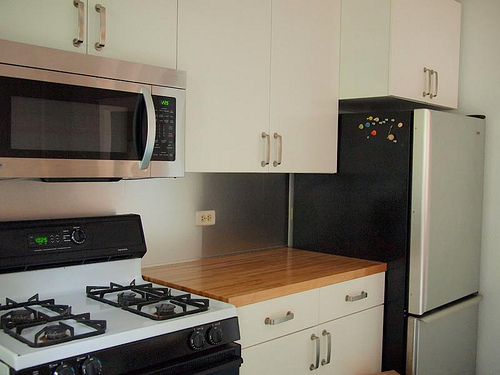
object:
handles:
[71, 0, 109, 51]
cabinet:
[179, 1, 343, 171]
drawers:
[232, 270, 386, 349]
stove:
[2, 278, 210, 347]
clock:
[24, 229, 64, 251]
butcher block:
[142, 245, 385, 310]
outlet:
[197, 208, 219, 226]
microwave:
[0, 75, 179, 160]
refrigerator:
[409, 107, 484, 314]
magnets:
[350, 109, 415, 148]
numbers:
[157, 98, 172, 108]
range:
[66, 229, 92, 248]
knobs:
[184, 325, 228, 348]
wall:
[0, 172, 288, 269]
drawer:
[235, 288, 322, 351]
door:
[3, 82, 135, 160]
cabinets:
[237, 268, 384, 373]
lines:
[217, 273, 261, 288]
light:
[37, 229, 55, 245]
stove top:
[0, 258, 240, 358]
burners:
[84, 278, 212, 321]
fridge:
[284, 110, 486, 375]